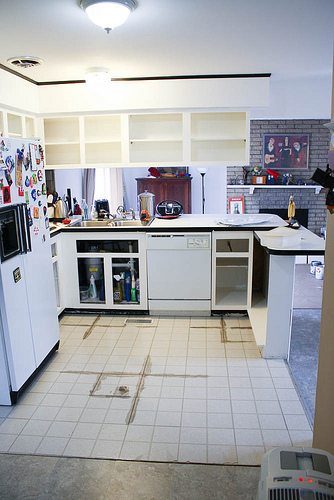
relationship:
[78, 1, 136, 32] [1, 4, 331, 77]
light on ceiling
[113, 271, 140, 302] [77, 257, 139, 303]
cleaning products in cabinet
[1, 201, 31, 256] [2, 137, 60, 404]
ice dispenser on fridge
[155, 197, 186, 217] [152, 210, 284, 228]
radio on kitchen counter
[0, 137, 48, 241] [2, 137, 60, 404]
magnets on fridge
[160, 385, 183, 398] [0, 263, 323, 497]
tile on floor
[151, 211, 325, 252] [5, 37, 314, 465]
countertop in kitchen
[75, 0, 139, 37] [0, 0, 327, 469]
light in kitchen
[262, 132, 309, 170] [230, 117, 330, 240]
art on wall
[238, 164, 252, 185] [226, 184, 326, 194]
item on mantle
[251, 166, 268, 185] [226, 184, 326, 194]
item on mantle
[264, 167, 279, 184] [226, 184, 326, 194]
item on mantle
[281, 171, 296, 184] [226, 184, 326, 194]
item on mantle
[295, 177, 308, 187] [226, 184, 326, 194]
item on mantle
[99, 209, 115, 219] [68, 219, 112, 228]
faucet over sink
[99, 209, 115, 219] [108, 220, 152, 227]
faucet over sink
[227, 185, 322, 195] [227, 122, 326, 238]
mantel on fireplace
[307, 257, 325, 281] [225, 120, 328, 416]
paint cans in room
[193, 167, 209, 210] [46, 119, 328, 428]
lamp in room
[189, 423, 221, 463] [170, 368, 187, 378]
grout between tiles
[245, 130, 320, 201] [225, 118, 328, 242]
bricks around brick fireplace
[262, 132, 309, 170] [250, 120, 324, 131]
art on wall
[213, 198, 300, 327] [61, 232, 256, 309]
cabinets on bottom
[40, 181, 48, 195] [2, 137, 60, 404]
magnets on fridge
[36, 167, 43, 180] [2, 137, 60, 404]
magnets on fridge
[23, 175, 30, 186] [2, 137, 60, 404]
magnets on fridge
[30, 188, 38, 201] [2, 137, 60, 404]
magnets on fridge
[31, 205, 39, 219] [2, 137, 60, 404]
magnets on fridge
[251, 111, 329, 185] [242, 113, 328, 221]
art on wall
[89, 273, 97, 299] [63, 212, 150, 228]
bottle underneath sink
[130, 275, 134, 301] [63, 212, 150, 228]
bottle underneath sink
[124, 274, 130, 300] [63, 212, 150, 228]
bottle underneath sink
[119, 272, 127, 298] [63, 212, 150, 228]
bottle underneath sink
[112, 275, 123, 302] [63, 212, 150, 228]
bottle underneath sink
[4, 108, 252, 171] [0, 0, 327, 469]
cabinet in kitchen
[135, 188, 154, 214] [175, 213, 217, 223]
pot on counter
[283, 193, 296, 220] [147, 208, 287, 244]
dish washing on counter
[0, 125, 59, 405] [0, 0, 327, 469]
refrigerator in kitchen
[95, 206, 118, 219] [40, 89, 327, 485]
faucet in kitchen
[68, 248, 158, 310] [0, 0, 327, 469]
cabinet in kitchen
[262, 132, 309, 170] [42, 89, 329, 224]
art on wall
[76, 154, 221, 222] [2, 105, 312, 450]
window in kitchen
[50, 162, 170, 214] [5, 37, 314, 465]
curtain in kitchen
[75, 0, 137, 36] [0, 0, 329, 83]
light on ceiling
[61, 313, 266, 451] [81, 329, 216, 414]
tiles on floor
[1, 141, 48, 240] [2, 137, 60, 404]
magnets on fridge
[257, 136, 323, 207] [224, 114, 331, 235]
bricks on wall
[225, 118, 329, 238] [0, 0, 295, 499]
brick fireplace beyond kitchen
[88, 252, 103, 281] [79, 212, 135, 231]
disposal under sink